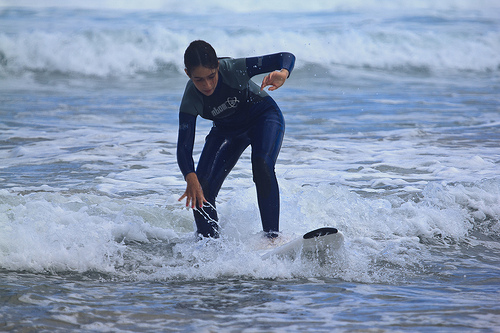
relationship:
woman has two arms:
[160, 35, 300, 238] [174, 52, 307, 210]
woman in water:
[160, 35, 300, 238] [1, 1, 482, 330]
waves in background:
[2, 27, 499, 83] [28, 229, 497, 282]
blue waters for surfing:
[1, 1, 482, 330] [172, 164, 299, 303]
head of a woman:
[183, 39, 225, 97] [175, 49, 228, 123]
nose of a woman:
[206, 80, 213, 89] [147, 50, 284, 164]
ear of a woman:
[181, 66, 190, 76] [174, 54, 274, 195]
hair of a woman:
[172, 39, 226, 73] [182, 50, 282, 174]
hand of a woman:
[261, 67, 290, 93] [172, 67, 282, 236]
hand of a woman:
[261, 67, 290, 93] [174, 67, 288, 295]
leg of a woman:
[254, 117, 285, 232] [183, 68, 261, 229]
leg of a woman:
[254, 117, 285, 232] [157, 67, 278, 312]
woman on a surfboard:
[160, 35, 300, 238] [135, 218, 319, 323]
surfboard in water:
[226, 226, 343, 266] [7, 184, 498, 304]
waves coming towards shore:
[5, 90, 498, 333] [8, 283, 498, 333]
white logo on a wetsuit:
[206, 98, 249, 116] [162, 68, 301, 245]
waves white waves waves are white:
[5, 140, 498, 277] [3, 32, 499, 82]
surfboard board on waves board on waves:
[226, 226, 343, 266] [244, 228, 368, 259]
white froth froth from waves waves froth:
[1, 190, 121, 277] [0, 33, 80, 70]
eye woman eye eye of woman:
[194, 74, 202, 82] [208, 73, 218, 78]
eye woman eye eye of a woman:
[194, 74, 202, 82] [209, 75, 218, 79]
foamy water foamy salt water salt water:
[1, 190, 121, 277] [0, 33, 80, 70]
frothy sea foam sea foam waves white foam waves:
[1, 190, 121, 277] [0, 33, 80, 70]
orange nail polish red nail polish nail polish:
[192, 205, 197, 207] [186, 203, 191, 207]